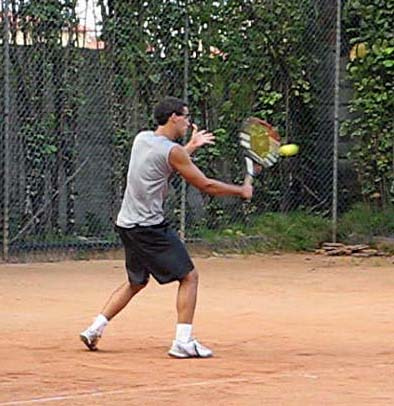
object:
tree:
[62, 26, 85, 234]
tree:
[47, 35, 67, 237]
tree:
[10, 6, 47, 239]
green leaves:
[69, 51, 78, 62]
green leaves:
[44, 143, 58, 157]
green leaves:
[23, 18, 36, 35]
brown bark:
[64, 188, 76, 227]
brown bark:
[50, 165, 58, 192]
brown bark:
[14, 67, 26, 97]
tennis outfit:
[116, 131, 194, 283]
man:
[76, 95, 254, 361]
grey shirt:
[114, 129, 179, 230]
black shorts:
[118, 224, 194, 285]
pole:
[330, 0, 344, 246]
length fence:
[0, 0, 394, 257]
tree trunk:
[63, 122, 78, 172]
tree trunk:
[46, 168, 61, 218]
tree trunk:
[27, 163, 40, 210]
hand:
[239, 182, 254, 200]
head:
[153, 94, 191, 139]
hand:
[190, 122, 217, 149]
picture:
[0, 0, 394, 406]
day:
[0, 0, 392, 406]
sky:
[73, 4, 105, 39]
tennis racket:
[231, 109, 285, 207]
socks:
[173, 322, 196, 344]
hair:
[148, 93, 188, 128]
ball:
[277, 142, 300, 159]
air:
[215, 78, 356, 211]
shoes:
[166, 335, 215, 360]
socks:
[89, 313, 111, 334]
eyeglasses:
[176, 110, 192, 121]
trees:
[101, 5, 128, 238]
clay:
[0, 252, 394, 406]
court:
[0, 238, 394, 406]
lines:
[7, 370, 296, 406]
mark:
[192, 343, 200, 357]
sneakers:
[77, 324, 106, 353]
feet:
[77, 325, 102, 353]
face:
[172, 106, 189, 136]